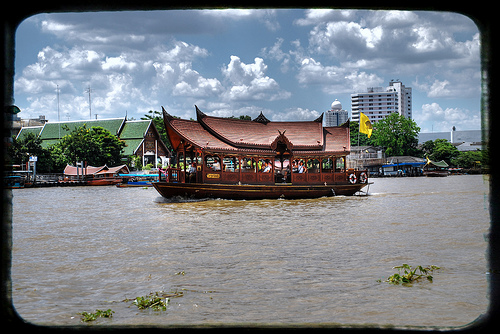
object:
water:
[3, 175, 490, 328]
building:
[347, 78, 417, 135]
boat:
[114, 176, 151, 190]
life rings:
[358, 169, 371, 186]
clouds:
[10, 2, 487, 135]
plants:
[70, 258, 442, 326]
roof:
[14, 117, 172, 160]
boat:
[418, 157, 454, 179]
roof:
[423, 158, 450, 169]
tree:
[47, 121, 130, 175]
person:
[186, 161, 199, 182]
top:
[328, 97, 346, 111]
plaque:
[203, 172, 226, 181]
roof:
[158, 102, 355, 162]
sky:
[11, 5, 488, 131]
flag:
[356, 111, 376, 160]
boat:
[147, 99, 377, 208]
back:
[324, 115, 380, 197]